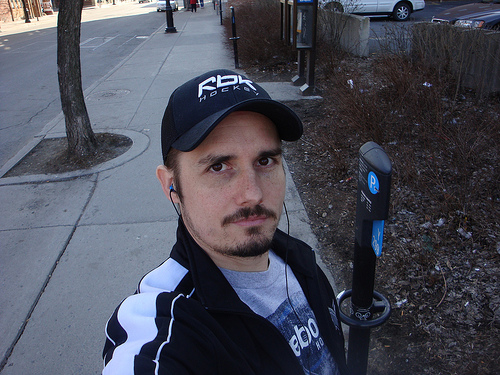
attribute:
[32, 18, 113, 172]
tree — growing, black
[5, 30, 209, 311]
sidewalk — concrete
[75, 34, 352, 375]
man — young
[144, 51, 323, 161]
cap — black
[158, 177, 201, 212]
earbud — blue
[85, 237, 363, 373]
jacket — white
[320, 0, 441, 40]
vehicle — white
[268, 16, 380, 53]
divider — concrete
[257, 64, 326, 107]
foundation — concrete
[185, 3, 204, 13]
pedestrian — walking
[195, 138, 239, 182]
eye — brown, black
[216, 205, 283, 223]
mustache — brown, neat, black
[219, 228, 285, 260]
goatee — brown, black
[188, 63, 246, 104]
letter — white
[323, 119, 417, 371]
pole — large, black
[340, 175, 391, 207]
object — blue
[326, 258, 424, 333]
hubcap — black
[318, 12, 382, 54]
wall — concrete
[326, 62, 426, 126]
weeds — brown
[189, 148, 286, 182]
eyes — focused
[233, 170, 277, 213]
nose — standard